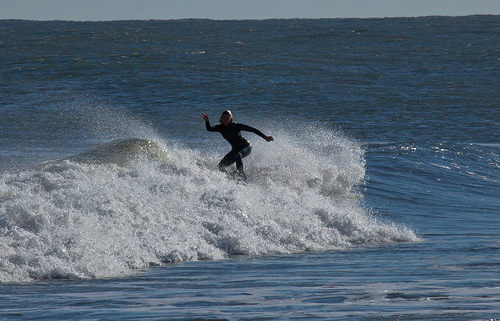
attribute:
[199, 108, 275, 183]
person — surfing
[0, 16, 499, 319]
water — blue, splashing, rippled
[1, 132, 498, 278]
waves — white, crashing, swelling, splashing, large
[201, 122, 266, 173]
wetsuit — black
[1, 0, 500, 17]
sky — blue, gray blue, clear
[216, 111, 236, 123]
hair — brown, dark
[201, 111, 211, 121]
hand — balancing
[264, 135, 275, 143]
hand — balancing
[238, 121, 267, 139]
arm — balancing, extended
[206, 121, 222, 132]
arm — balancing